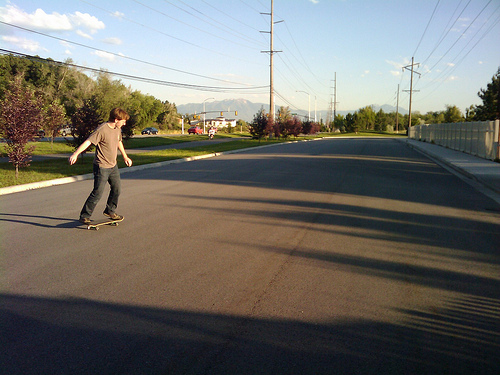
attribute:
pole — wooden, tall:
[257, 2, 282, 121]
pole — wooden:
[405, 59, 418, 126]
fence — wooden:
[407, 120, 500, 161]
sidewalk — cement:
[400, 136, 499, 207]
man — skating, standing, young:
[67, 107, 135, 222]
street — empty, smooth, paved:
[0, 138, 499, 375]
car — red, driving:
[187, 124, 205, 137]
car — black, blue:
[142, 124, 161, 137]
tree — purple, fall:
[2, 72, 45, 173]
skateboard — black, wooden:
[76, 212, 127, 232]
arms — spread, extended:
[62, 125, 132, 171]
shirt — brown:
[90, 123, 123, 170]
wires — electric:
[1, 19, 261, 93]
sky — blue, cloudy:
[7, 0, 497, 117]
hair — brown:
[108, 106, 132, 126]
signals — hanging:
[188, 111, 248, 119]